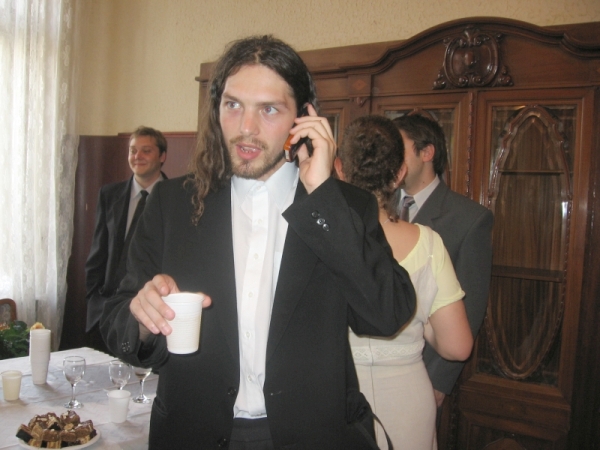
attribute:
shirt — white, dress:
[225, 161, 293, 440]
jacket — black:
[112, 170, 415, 446]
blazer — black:
[103, 168, 419, 446]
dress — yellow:
[350, 226, 460, 444]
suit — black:
[80, 180, 167, 373]